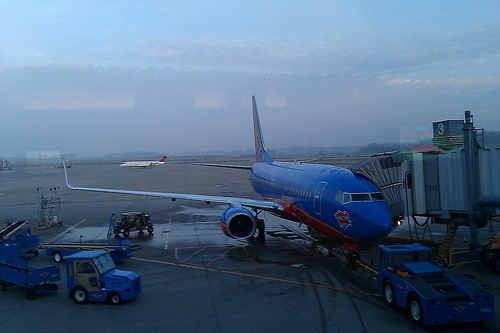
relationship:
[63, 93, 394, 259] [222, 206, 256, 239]
plane has engine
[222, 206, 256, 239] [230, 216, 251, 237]
engine has turbine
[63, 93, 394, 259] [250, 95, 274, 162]
plane has fin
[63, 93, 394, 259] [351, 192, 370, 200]
plane has window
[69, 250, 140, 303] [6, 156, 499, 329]
vehicle driving on tarmac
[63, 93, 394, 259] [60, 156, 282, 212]
plane has wing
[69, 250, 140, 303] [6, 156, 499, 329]
vehicle on top of tarmac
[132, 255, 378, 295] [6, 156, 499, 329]
line on top of tarmac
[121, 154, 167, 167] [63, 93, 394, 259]
plane behind plane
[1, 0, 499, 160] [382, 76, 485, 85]
sky has cloud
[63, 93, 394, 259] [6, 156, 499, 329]
plane on top of tarmac